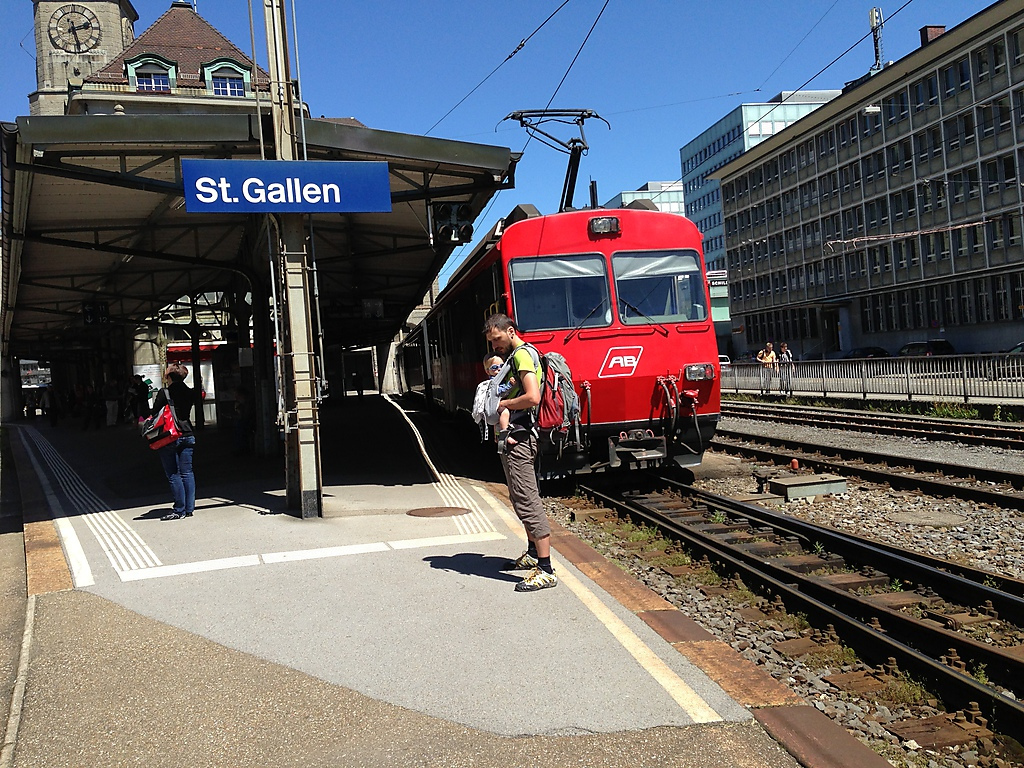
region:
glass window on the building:
[713, 175, 739, 199]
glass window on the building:
[731, 172, 750, 193]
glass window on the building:
[787, 138, 811, 159]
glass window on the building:
[836, 112, 853, 136]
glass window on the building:
[855, 100, 879, 124]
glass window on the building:
[728, 210, 751, 230]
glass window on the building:
[789, 177, 819, 206]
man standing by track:
[462, 312, 584, 594]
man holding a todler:
[465, 350, 522, 452]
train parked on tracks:
[371, 194, 741, 501]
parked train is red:
[376, 194, 731, 493]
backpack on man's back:
[531, 347, 582, 453]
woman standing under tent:
[140, 347, 217, 526]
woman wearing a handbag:
[137, 378, 180, 451]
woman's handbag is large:
[140, 382, 180, 458]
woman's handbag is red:
[134, 381, 182, 454]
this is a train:
[321, 168, 752, 523]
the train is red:
[302, 165, 784, 549]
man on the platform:
[438, 284, 607, 627]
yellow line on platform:
[454, 467, 752, 759]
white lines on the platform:
[16, 407, 519, 626]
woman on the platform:
[125, 322, 266, 583]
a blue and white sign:
[149, 121, 437, 252]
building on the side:
[693, 0, 1014, 365]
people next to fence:
[743, 304, 816, 410]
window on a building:
[985, 37, 1001, 66]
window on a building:
[130, 67, 170, 90]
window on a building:
[212, 70, 248, 97]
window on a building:
[1004, 209, 1017, 236]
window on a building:
[891, 237, 902, 264]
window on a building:
[906, 233, 922, 259]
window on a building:
[780, 224, 800, 253]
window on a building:
[821, 212, 835, 231]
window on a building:
[862, 198, 879, 222]